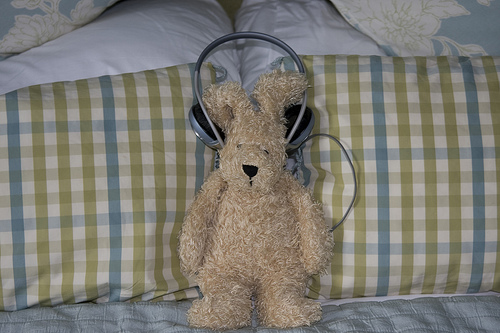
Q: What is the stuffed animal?
A: Rabbit.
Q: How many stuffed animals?
A: 1.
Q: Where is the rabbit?
A: On a bed.